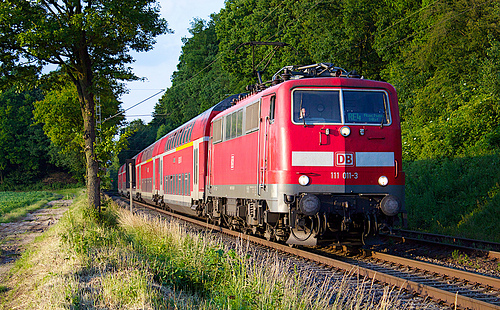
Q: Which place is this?
A: It is a forest.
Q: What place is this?
A: It is a forest.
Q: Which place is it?
A: It is a forest.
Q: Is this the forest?
A: Yes, it is the forest.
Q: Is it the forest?
A: Yes, it is the forest.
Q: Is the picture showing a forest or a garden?
A: It is showing a forest.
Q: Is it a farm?
A: No, it is a forest.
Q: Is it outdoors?
A: Yes, it is outdoors.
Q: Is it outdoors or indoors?
A: It is outdoors.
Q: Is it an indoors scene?
A: No, it is outdoors.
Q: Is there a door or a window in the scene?
A: Yes, there is a window.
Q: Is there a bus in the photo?
A: No, there are no buses.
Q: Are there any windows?
A: Yes, there is a window.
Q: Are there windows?
A: Yes, there is a window.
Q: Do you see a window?
A: Yes, there is a window.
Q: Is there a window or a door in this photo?
A: Yes, there is a window.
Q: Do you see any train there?
A: Yes, there is a train.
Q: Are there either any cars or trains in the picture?
A: Yes, there is a train.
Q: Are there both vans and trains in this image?
A: No, there is a train but no vans.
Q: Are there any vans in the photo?
A: No, there are no vans.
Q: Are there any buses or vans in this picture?
A: No, there are no vans or buses.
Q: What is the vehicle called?
A: The vehicle is a train.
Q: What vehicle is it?
A: The vehicle is a train.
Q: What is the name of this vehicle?
A: This is a train.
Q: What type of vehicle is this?
A: This is a train.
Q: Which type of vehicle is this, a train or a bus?
A: This is a train.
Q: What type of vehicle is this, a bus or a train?
A: This is a train.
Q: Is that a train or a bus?
A: That is a train.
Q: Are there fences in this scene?
A: No, there are no fences.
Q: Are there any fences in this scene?
A: No, there are no fences.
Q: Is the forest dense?
A: Yes, the forest is dense.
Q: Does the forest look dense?
A: Yes, the forest is dense.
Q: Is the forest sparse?
A: No, the forest is dense.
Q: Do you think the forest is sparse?
A: No, the forest is dense.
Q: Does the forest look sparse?
A: No, the forest is dense.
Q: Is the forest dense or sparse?
A: The forest is dense.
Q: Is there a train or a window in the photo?
A: Yes, there is a window.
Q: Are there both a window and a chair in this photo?
A: No, there is a window but no chairs.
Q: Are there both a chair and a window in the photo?
A: No, there is a window but no chairs.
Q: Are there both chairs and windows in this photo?
A: No, there is a window but no chairs.